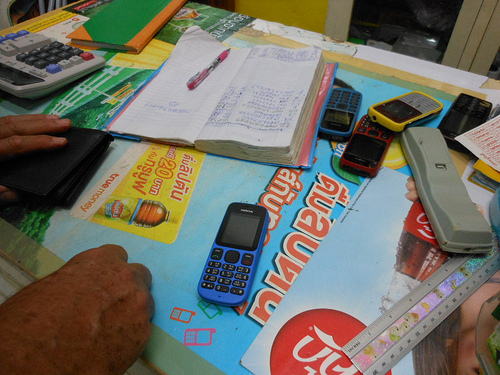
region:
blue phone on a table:
[199, 195, 268, 308]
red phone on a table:
[344, 113, 394, 176]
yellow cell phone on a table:
[374, 86, 436, 133]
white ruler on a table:
[346, 242, 490, 372]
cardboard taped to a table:
[0, 0, 497, 370]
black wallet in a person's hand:
[0, 113, 115, 212]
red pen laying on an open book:
[188, 46, 229, 88]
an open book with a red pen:
[114, 22, 336, 167]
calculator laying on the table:
[0, 32, 107, 97]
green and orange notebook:
[67, 0, 182, 52]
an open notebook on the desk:
[110, 25, 342, 175]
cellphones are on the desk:
[195, 73, 440, 318]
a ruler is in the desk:
[335, 221, 498, 371]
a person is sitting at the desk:
[4, 104, 175, 372]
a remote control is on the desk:
[394, 119, 497, 269]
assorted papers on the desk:
[9, 2, 496, 366]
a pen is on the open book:
[179, 37, 240, 98]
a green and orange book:
[64, 1, 193, 57]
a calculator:
[3, 22, 106, 102]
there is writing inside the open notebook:
[141, 29, 340, 181]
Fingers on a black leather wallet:
[0, 112, 112, 212]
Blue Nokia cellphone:
[196, 200, 270, 307]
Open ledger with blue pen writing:
[105, 22, 340, 170]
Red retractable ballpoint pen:
[185, 46, 237, 91]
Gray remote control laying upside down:
[400, 123, 493, 258]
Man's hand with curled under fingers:
[1, 241, 155, 373]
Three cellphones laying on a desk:
[315, 85, 445, 179]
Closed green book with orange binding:
[67, 0, 189, 54]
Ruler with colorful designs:
[342, 234, 499, 374]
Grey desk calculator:
[0, 28, 106, 100]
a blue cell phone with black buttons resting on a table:
[197, 200, 269, 307]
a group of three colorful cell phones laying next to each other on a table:
[317, 85, 444, 177]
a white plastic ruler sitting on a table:
[341, 235, 499, 373]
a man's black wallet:
[1, 125, 114, 208]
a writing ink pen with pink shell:
[187, 47, 231, 90]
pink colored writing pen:
[187, 46, 232, 92]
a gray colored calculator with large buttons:
[0, 28, 107, 99]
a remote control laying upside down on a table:
[398, 125, 493, 253]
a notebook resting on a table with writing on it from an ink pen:
[100, 23, 338, 170]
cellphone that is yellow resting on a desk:
[368, 89, 444, 133]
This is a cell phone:
[189, 178, 273, 325]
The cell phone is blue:
[203, 178, 260, 314]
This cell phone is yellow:
[367, 70, 449, 133]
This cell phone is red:
[329, 130, 392, 175]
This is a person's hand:
[9, 250, 161, 371]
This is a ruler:
[347, 259, 463, 368]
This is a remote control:
[396, 128, 493, 252]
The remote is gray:
[388, 138, 495, 276]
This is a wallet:
[2, 123, 109, 198]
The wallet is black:
[16, 115, 116, 208]